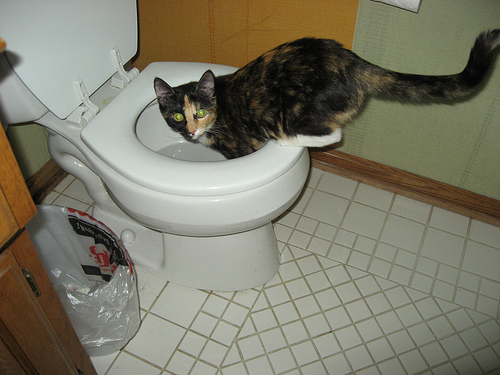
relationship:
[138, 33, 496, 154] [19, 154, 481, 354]
cat in bathroom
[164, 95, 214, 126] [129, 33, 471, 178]
green eyes on cat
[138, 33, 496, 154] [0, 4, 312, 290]
cat on toilet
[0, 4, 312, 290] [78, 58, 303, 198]
toilet with seat up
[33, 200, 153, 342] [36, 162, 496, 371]
can on floor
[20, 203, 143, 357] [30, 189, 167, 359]
bag in trash can